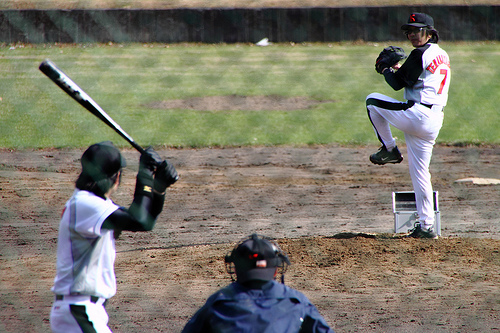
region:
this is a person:
[346, 11, 461, 248]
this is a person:
[194, 223, 343, 332]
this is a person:
[46, 151, 177, 331]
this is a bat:
[33, 57, 186, 184]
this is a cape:
[221, 227, 291, 282]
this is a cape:
[61, 137, 136, 191]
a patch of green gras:
[191, 96, 266, 146]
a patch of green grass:
[124, 66, 163, 100]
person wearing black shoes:
[364, 1, 453, 234]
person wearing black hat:
[356, 8, 456, 234]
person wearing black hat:
[64, 137, 168, 330]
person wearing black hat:
[183, 240, 330, 330]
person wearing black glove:
[365, 14, 453, 239]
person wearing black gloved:
[65, 140, 168, 327]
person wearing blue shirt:
[187, 238, 330, 330]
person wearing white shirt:
[54, 146, 174, 324]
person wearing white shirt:
[373, 0, 456, 237]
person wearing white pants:
[367, 17, 456, 241]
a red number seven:
[438, 67, 448, 98]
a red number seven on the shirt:
[434, 67, 449, 99]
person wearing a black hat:
[406, 7, 436, 29]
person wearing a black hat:
[81, 142, 126, 171]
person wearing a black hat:
[237, 242, 278, 282]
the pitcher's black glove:
[376, 45, 406, 68]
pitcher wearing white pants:
[360, 105, 442, 235]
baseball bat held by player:
[39, 56, 144, 148]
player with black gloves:
[146, 150, 180, 179]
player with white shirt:
[57, 196, 114, 298]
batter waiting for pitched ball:
[34, 55, 182, 330]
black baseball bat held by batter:
[34, 56, 179, 183]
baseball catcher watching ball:
[178, 233, 338, 332]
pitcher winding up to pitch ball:
[365, 9, 454, 241]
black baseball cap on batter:
[83, 139, 134, 184]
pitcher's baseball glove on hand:
[374, 44, 408, 73]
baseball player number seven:
[359, 8, 451, 241]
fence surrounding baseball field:
[5, 6, 498, 43]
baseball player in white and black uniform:
[365, 11, 452, 242]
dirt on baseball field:
[3, 133, 497, 331]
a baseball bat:
[42, 61, 67, 86]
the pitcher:
[358, 14, 453, 234]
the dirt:
[230, 187, 308, 223]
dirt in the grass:
[196, 86, 283, 113]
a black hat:
[86, 145, 113, 170]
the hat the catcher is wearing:
[239, 244, 274, 280]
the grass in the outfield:
[137, 47, 236, 78]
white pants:
[411, 157, 436, 224]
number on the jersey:
[434, 68, 449, 98]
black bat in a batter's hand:
[33, 56, 173, 186]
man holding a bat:
[51, 135, 179, 331]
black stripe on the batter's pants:
[68, 303, 101, 332]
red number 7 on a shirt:
[437, 68, 448, 95]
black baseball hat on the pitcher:
[403, 10, 437, 30]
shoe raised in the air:
[368, 143, 405, 165]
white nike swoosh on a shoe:
[377, 153, 391, 164]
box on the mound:
[386, 185, 443, 236]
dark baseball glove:
[374, 40, 406, 75]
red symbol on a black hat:
[406, 13, 418, 21]